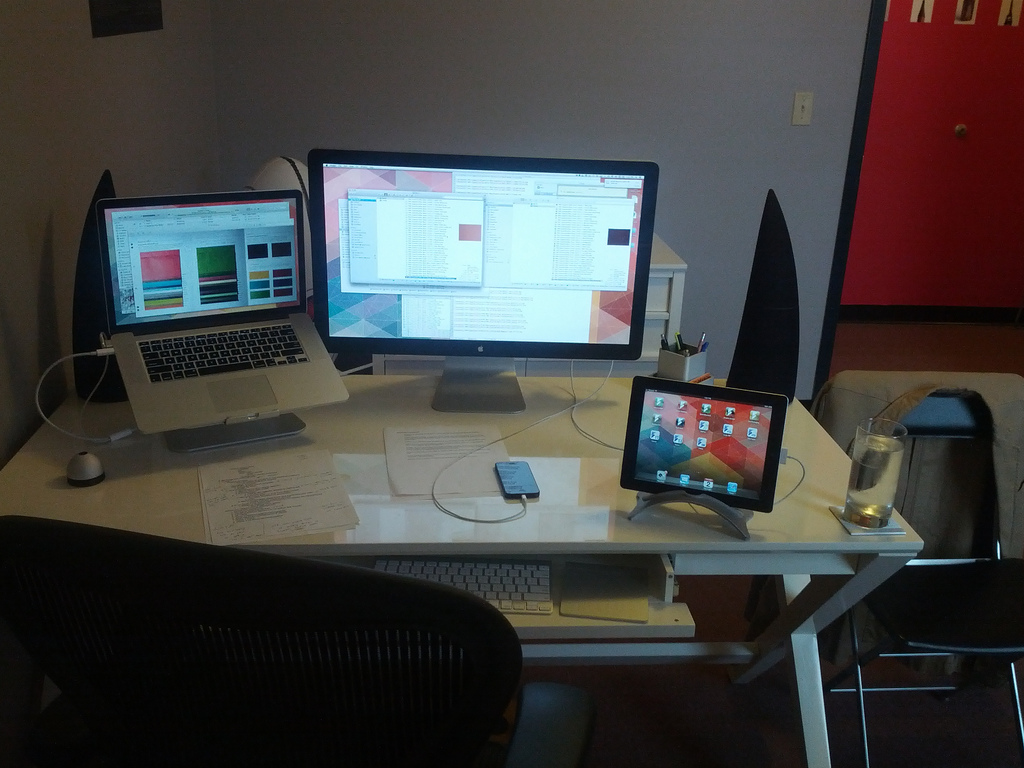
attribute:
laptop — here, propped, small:
[104, 198, 336, 419]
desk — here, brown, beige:
[103, 495, 177, 531]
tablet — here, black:
[621, 361, 772, 502]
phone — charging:
[499, 459, 538, 497]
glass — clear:
[848, 419, 893, 532]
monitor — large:
[305, 136, 649, 373]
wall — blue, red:
[419, 40, 643, 98]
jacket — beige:
[908, 371, 994, 401]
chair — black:
[883, 452, 1015, 707]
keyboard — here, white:
[371, 550, 553, 616]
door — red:
[844, 37, 989, 295]